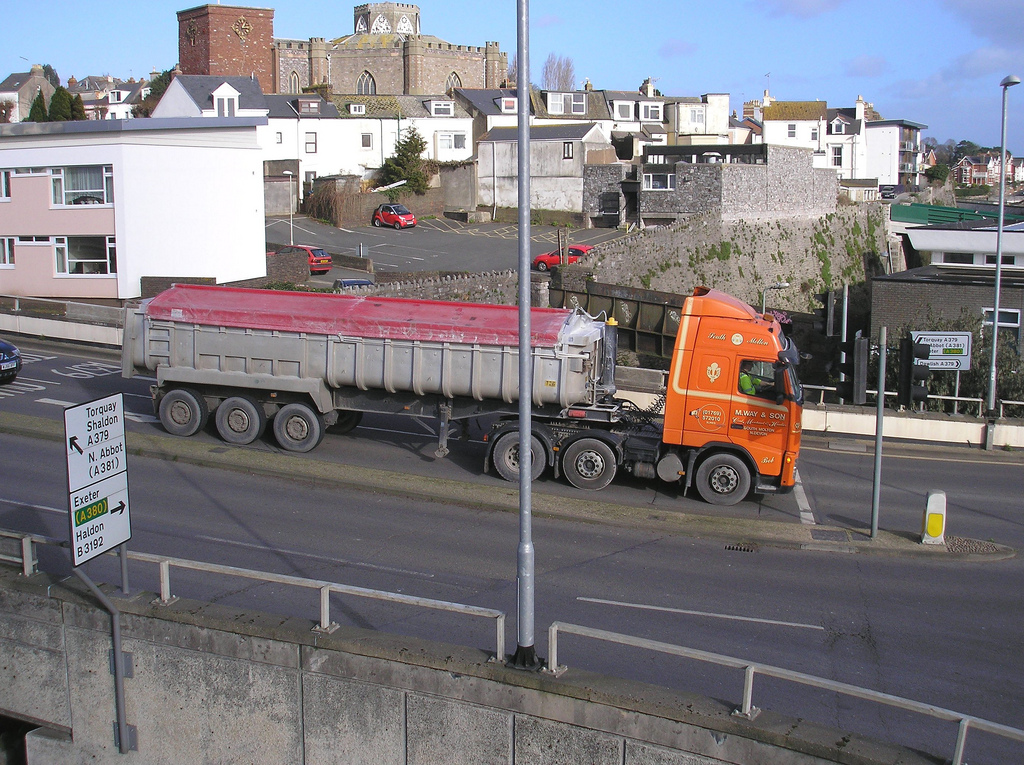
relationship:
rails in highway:
[2, 528, 1023, 762] [11, 363, 984, 740]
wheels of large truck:
[153, 379, 759, 511] [125, 282, 810, 508]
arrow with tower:
[67, 433, 89, 460] [351, 1, 419, 39]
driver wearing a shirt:
[736, 353, 773, 405] [741, 371, 755, 395]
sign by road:
[54, 399, 134, 494] [2, 333, 1023, 761]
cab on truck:
[662, 283, 796, 496] [119, 240, 800, 494]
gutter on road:
[693, 523, 807, 565] [208, 474, 990, 703]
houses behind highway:
[3, 62, 939, 215] [2, 308, 1023, 762]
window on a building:
[39, 162, 122, 213] [103, 85, 380, 369]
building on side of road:
[1, 74, 283, 315] [191, 454, 993, 722]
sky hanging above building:
[19, 5, 1016, 157] [175, 3, 515, 103]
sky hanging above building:
[19, 5, 1016, 157] [143, 68, 349, 205]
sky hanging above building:
[19, 5, 1016, 157] [4, 113, 275, 295]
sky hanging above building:
[19, 5, 1016, 157] [272, 89, 409, 204]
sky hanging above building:
[19, 5, 1016, 157] [385, 91, 476, 169]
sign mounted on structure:
[46, 379, 149, 573] [6, 560, 944, 761]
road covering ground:
[7, 286, 1011, 762] [6, 323, 992, 758]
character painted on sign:
[68, 542, 78, 556] [60, 389, 140, 569]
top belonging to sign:
[60, 387, 128, 457] [60, 389, 140, 569]